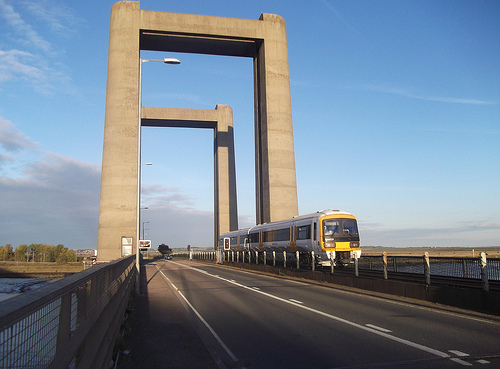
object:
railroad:
[166, 208, 500, 293]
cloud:
[22, 124, 98, 245]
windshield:
[322, 218, 360, 243]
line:
[160, 258, 473, 365]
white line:
[150, 261, 239, 360]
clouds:
[323, 61, 431, 118]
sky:
[0, 0, 499, 251]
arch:
[96, 0, 298, 263]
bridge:
[0, 0, 500, 369]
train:
[218, 209, 361, 269]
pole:
[134, 57, 141, 297]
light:
[142, 58, 181, 65]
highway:
[118, 257, 500, 369]